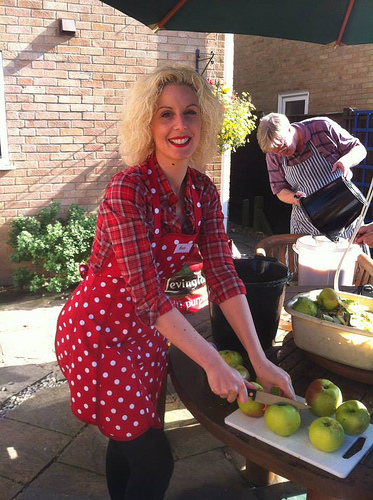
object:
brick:
[24, 118, 49, 128]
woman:
[56, 61, 296, 499]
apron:
[55, 153, 202, 438]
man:
[255, 112, 371, 284]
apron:
[282, 143, 370, 274]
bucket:
[299, 177, 367, 242]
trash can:
[211, 256, 288, 347]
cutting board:
[223, 393, 372, 479]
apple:
[309, 416, 345, 454]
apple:
[306, 377, 342, 417]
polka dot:
[110, 360, 116, 366]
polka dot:
[121, 412, 130, 423]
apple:
[264, 403, 300, 436]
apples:
[335, 396, 368, 434]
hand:
[206, 363, 256, 403]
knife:
[241, 378, 314, 411]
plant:
[207, 77, 257, 158]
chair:
[350, 253, 373, 284]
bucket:
[292, 234, 360, 285]